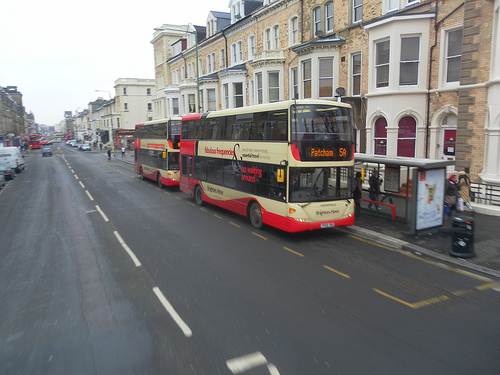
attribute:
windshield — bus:
[289, 163, 356, 201]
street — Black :
[0, 140, 500, 372]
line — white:
[149, 281, 197, 341]